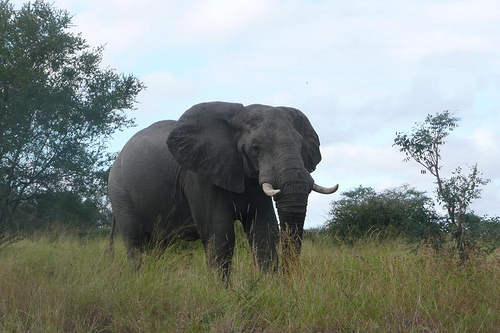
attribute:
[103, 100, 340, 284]
elephant — dark grey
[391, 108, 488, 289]
tree — big 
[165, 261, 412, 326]
grass — tall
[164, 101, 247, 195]
ear — floppy , large 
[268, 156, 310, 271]
trunk — gray , large 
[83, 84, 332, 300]
elephant — gray 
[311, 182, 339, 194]
tusk — white, sharp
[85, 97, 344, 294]
elephant — gray , big 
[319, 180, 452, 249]
bush — green , little 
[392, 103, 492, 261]
tree — small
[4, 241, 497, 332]
grass — tall, dry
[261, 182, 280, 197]
right tusk — little , white 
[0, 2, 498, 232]
sky — clear, blue 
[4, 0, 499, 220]
clouds — fluffy 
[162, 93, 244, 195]
ear — large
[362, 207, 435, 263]
grass — Tall 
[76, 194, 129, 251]
tail — thin , little 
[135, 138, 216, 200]
skin — gray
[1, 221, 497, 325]
field — full 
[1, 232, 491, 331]
grass — green 